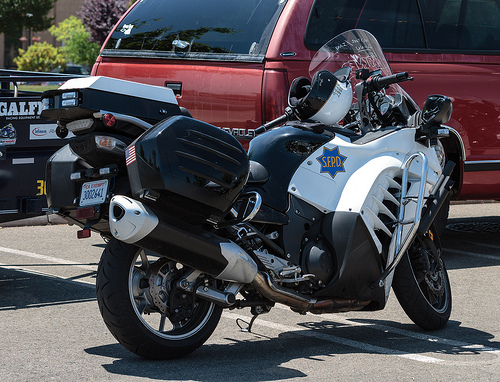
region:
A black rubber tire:
[85, 230, 230, 361]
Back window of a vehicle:
[97, 0, 287, 71]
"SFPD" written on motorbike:
[315, 146, 345, 171]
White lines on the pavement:
[0, 235, 497, 370]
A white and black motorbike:
[32, 20, 472, 361]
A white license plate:
[70, 170, 111, 210]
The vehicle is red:
[82, 0, 497, 202]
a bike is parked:
[62, 44, 404, 370]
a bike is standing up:
[83, 20, 468, 373]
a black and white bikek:
[35, 33, 489, 368]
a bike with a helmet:
[72, 43, 475, 343]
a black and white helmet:
[271, 58, 401, 157]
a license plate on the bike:
[40, 63, 457, 361]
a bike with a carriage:
[19, 34, 454, 363]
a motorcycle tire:
[78, 201, 248, 353]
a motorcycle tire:
[397, 205, 482, 355]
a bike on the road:
[49, 56, 496, 341]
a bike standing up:
[50, 65, 475, 361]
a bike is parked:
[85, 47, 482, 377]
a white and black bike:
[62, 25, 467, 339]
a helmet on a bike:
[96, 29, 428, 316]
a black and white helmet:
[279, 50, 351, 116]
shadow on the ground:
[157, 311, 357, 379]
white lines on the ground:
[254, 283, 491, 376]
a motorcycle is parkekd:
[139, 63, 443, 347]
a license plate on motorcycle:
[77, 175, 110, 211]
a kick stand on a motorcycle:
[234, 303, 271, 338]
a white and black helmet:
[282, 55, 357, 126]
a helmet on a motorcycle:
[287, 57, 354, 140]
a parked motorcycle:
[47, 26, 470, 355]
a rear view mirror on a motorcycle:
[423, 87, 459, 129]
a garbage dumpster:
[0, 63, 62, 234]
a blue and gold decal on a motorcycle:
[315, 145, 350, 177]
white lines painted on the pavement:
[8, 232, 97, 300]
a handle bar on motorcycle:
[356, 65, 411, 118]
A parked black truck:
[0, 61, 90, 223]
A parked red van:
[89, 0, 499, 210]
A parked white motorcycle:
[39, 27, 468, 357]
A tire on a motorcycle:
[389, 228, 453, 329]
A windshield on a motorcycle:
[307, 23, 409, 105]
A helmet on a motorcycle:
[285, 65, 357, 127]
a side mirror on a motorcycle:
[421, 88, 455, 149]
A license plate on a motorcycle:
[73, 176, 113, 208]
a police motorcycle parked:
[35, 28, 465, 352]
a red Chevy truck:
[90, 0, 498, 240]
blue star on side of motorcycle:
[317, 145, 346, 177]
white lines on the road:
[400, 308, 487, 365]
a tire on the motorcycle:
[398, 205, 468, 343]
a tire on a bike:
[111, 220, 232, 360]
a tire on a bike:
[398, 220, 474, 375]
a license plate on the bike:
[61, 170, 94, 205]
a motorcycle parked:
[67, 52, 489, 334]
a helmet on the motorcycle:
[287, 68, 381, 119]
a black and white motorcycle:
[188, 58, 388, 243]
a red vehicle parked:
[101, 40, 390, 216]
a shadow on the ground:
[166, 282, 351, 374]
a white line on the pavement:
[350, 305, 494, 378]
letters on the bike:
[321, 149, 353, 189]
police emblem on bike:
[314, 142, 351, 178]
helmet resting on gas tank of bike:
[287, 62, 359, 129]